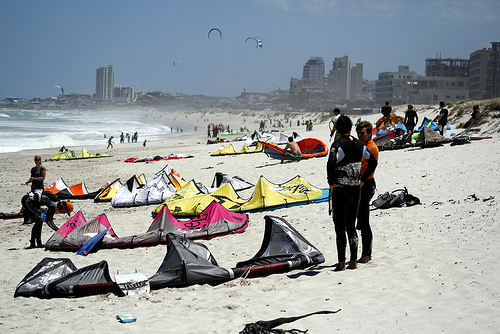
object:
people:
[21, 155, 46, 190]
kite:
[13, 215, 325, 298]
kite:
[151, 174, 332, 219]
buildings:
[375, 65, 412, 107]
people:
[280, 137, 302, 164]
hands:
[330, 184, 337, 194]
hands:
[359, 181, 364, 188]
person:
[350, 119, 380, 264]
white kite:
[244, 36, 263, 49]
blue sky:
[1, 0, 500, 100]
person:
[347, 115, 378, 262]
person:
[323, 112, 368, 269]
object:
[116, 314, 138, 324]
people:
[106, 136, 116, 149]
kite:
[244, 37, 263, 49]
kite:
[208, 28, 223, 39]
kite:
[173, 60, 181, 66]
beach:
[1, 103, 500, 332]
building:
[96, 64, 115, 102]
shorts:
[282, 151, 302, 160]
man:
[21, 191, 73, 248]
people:
[436, 101, 448, 136]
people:
[327, 116, 378, 271]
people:
[143, 139, 148, 147]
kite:
[45, 199, 249, 251]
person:
[353, 111, 381, 260]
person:
[404, 97, 418, 155]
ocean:
[0, 114, 174, 153]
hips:
[332, 185, 360, 198]